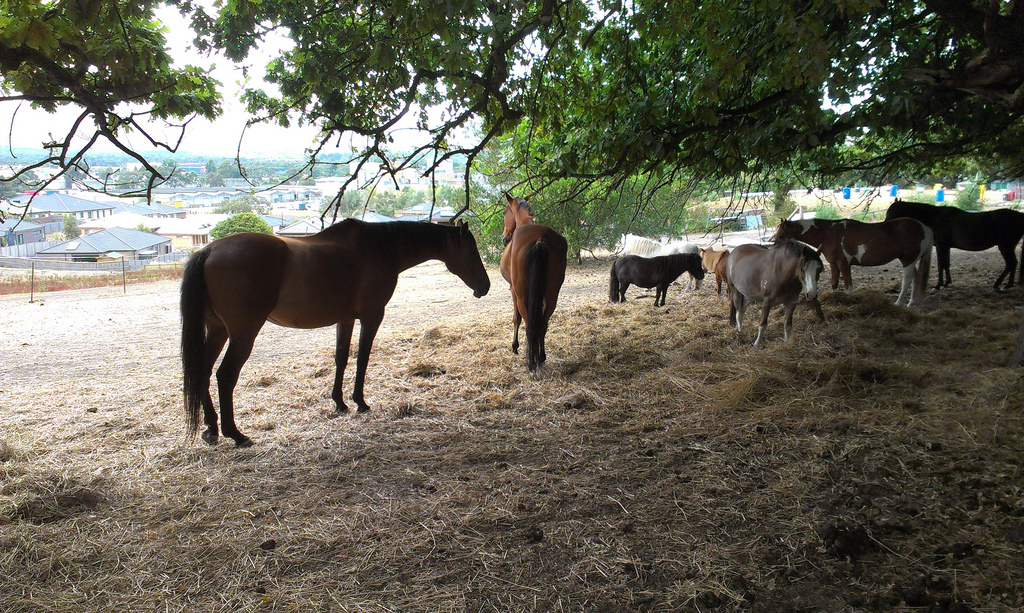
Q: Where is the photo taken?
A: In the field.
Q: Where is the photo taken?
A: In a pasture.